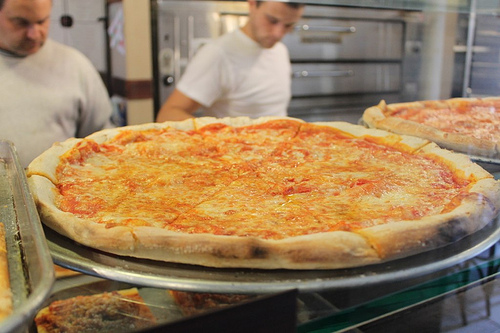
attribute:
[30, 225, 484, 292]
pan — silver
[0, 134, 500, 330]
shelf — glass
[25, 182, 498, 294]
pan — silver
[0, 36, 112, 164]
shirt — light grey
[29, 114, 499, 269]
pizza — crusty, cheese, big, spicy, flat, large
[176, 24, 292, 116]
t-shirt — white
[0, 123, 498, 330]
table — glass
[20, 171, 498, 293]
tray — gray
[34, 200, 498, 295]
tray — gray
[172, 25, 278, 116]
t-shirt — white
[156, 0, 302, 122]
man — light skinned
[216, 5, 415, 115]
pizza oven — stainless steel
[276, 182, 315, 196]
sauce — red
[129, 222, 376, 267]
crust — tan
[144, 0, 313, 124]
man — white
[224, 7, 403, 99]
doors — metal, oven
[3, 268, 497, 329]
window — pizza shop, glass display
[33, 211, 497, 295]
pan — metal, pizza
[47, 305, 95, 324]
sauce — red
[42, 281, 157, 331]
slice — pizza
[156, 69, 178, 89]
knob — black, metal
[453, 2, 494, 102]
trays — standing, silver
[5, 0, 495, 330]
kitchen — commercial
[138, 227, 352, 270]
crust — cooked, tan, pizza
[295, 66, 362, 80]
handle — metal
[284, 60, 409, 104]
door — oven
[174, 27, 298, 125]
tshirt — white, short sleeve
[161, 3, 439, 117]
oven — metallic, pizza, large, metal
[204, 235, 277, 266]
crust — pizza, crisp, section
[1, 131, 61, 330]
pan — steel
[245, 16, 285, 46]
hair — facial